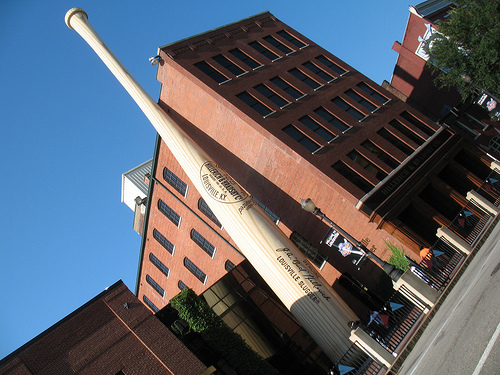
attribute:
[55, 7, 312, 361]
bat — giant baseball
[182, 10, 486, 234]
building — high rise 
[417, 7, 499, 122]
tree — leafy green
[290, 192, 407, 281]
lamp post — black metal lamp 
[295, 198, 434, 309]
street lamp — for  street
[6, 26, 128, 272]
sky — clear blue 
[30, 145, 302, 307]
building — red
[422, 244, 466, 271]
gate — black metal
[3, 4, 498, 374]
picture — slanted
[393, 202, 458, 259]
doorway — door  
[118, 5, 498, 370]
building — unique , unsual picture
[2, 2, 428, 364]
sky — clear blue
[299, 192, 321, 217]
lamp — street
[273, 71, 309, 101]
window —  dark,  Building's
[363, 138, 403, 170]
window —  dark,  Building's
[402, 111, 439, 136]
window —  dark,  Building's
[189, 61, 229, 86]
window —  dark,  Building's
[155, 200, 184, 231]
window —  dark,  Building's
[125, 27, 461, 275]
building — red brick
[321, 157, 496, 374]
fence — black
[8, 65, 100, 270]
sky —  clear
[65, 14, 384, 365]
ruth — Babe 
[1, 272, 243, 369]
building — side 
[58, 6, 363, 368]
bat — large baseball, largest , large, wooden, baseball, wood